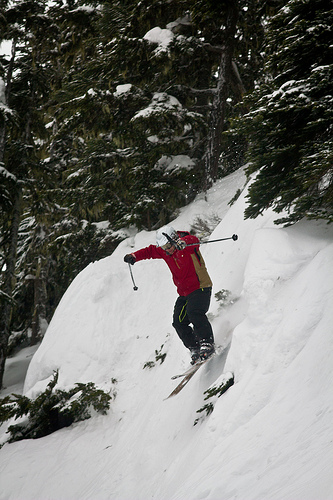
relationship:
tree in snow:
[1, 0, 71, 388] [161, 387, 199, 409]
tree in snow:
[1, 0, 71, 388] [0, 161, 330, 498]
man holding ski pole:
[123, 224, 214, 360] [182, 234, 242, 247]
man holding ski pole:
[123, 224, 214, 360] [121, 255, 141, 292]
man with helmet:
[126, 224, 223, 380] [151, 222, 171, 252]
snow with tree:
[0, 161, 330, 498] [189, 0, 270, 193]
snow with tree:
[0, 161, 330, 498] [16, 0, 67, 343]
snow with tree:
[0, 161, 330, 498] [0, 0, 28, 387]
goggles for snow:
[154, 240, 169, 246] [242, 236, 314, 319]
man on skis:
[123, 224, 214, 360] [165, 340, 232, 402]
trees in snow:
[4, 113, 331, 233] [0, 161, 330, 498]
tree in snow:
[224, 0, 331, 227] [243, 310, 328, 498]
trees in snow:
[130, 0, 266, 188] [243, 310, 328, 498]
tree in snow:
[0, 369, 118, 445] [243, 310, 328, 498]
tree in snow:
[1, 0, 71, 388] [243, 310, 328, 498]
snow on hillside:
[259, 234, 290, 275] [2, 197, 331, 497]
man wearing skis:
[123, 224, 214, 360] [162, 360, 212, 397]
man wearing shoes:
[123, 224, 214, 360] [186, 339, 212, 358]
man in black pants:
[123, 224, 214, 360] [173, 296, 211, 348]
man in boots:
[123, 224, 214, 360] [182, 335, 216, 365]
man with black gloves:
[123, 224, 214, 360] [122, 254, 140, 263]